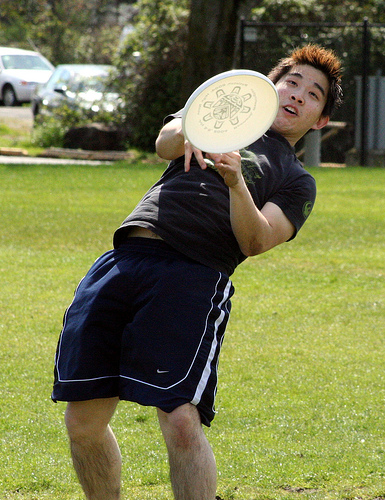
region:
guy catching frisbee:
[59, 63, 285, 496]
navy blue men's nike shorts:
[34, 229, 242, 433]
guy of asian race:
[252, 44, 333, 163]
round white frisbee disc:
[169, 61, 269, 171]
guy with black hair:
[255, 34, 343, 162]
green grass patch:
[34, 180, 97, 230]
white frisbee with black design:
[178, 64, 269, 164]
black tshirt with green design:
[266, 182, 314, 246]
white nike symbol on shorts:
[149, 362, 218, 419]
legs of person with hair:
[28, 388, 218, 495]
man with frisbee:
[41, 42, 339, 497]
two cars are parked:
[0, 17, 147, 164]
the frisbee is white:
[177, 67, 280, 155]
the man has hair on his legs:
[53, 391, 235, 498]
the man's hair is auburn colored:
[247, 34, 354, 148]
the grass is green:
[3, 161, 384, 498]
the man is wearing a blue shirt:
[96, 97, 335, 277]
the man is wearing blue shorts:
[46, 233, 236, 431]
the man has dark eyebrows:
[257, 43, 354, 153]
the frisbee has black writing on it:
[190, 77, 267, 138]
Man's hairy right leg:
[67, 433, 125, 495]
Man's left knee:
[153, 404, 205, 460]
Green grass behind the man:
[10, 172, 113, 222]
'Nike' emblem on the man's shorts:
[150, 362, 171, 376]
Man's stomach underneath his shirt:
[125, 221, 161, 241]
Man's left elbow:
[239, 220, 261, 258]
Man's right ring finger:
[194, 148, 207, 171]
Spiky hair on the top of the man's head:
[292, 37, 339, 73]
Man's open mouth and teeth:
[281, 102, 300, 119]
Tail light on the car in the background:
[14, 76, 29, 87]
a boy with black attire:
[53, 106, 292, 401]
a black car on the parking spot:
[33, 46, 132, 137]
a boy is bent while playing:
[53, 24, 380, 467]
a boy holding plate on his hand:
[170, 53, 291, 177]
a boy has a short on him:
[30, 207, 253, 407]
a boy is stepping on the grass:
[44, 397, 249, 498]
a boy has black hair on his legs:
[66, 435, 226, 488]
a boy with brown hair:
[298, 28, 349, 85]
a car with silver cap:
[4, 91, 13, 102]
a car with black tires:
[9, 84, 15, 97]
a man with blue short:
[37, 214, 323, 429]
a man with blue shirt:
[114, 91, 284, 253]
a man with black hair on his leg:
[161, 419, 222, 492]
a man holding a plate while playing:
[155, 58, 284, 172]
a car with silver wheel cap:
[5, 88, 14, 101]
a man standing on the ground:
[60, 249, 231, 498]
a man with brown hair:
[285, 26, 357, 73]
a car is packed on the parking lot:
[29, 62, 129, 134]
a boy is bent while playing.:
[72, 23, 373, 467]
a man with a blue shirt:
[97, 70, 324, 271]